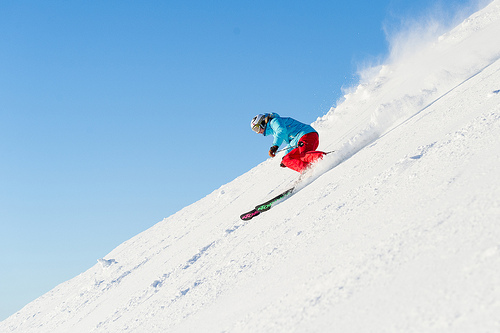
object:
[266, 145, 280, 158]
hand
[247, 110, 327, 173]
person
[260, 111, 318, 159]
jacket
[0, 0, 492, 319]
blue sky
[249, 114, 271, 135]
goggle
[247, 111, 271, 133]
helmet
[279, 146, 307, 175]
leg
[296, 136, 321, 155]
thigh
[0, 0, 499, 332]
snow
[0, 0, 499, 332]
ground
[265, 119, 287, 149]
arm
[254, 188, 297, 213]
ski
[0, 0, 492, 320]
cloud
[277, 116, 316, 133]
back